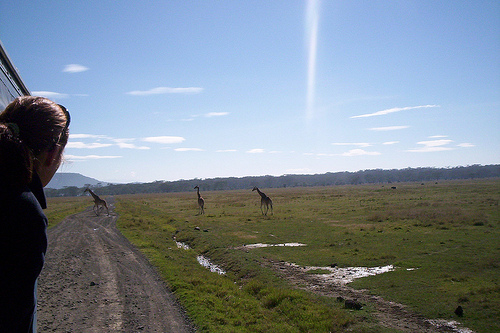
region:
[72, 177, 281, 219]
Three giraffes in front of the woman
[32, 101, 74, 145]
Glasses on the woman's head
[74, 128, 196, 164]
White clouds in the sky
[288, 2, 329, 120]
A thin white contrail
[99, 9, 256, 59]
The open blue sky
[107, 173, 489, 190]
Trees in the distance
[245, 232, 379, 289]
The plains are wet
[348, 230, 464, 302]
The grass is cut short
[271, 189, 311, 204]
Tall grass behind the giraffes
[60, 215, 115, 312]
A dirt path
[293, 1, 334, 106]
a white streak in the sky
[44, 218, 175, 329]
a brown dirt road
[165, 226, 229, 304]
water in a grassy ditch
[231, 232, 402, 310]
water puddles in the grassland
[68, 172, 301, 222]
three giraffes walking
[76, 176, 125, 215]
a giraffe crossing the road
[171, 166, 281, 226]
two giraffes following the first giraffe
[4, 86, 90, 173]
the back of a woman's head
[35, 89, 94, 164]
a pair of black sunglasses on a woman's head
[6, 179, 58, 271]
a blue sweater on a woman's shoulder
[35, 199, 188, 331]
a dirt road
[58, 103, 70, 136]
sunglasses on a woman's head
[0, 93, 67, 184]
brown hair pulled back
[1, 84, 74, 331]
a woman leaning out of a bus window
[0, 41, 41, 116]
the top of a bus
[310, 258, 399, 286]
watery mud in a field next to the road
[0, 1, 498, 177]
a blue sky with thin white clouds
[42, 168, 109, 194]
a mountain in the distance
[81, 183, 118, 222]
a giraffe on the road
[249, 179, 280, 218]
a giraffe in a field by the road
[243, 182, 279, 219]
giraffe in natural habitat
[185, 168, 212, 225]
giraffe in natural habitat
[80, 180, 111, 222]
giraffe in natural habitat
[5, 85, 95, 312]
person looking at giraffes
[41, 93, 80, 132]
sunglasses on top of head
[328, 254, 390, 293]
patch of water on field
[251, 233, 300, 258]
patch of water on field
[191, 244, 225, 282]
patch of water on field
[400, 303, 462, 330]
patch of water on field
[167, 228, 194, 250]
patch of water on field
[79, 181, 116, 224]
giraffe walking over the road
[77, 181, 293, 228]
group of giraffes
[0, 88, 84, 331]
person looking at a group of giraffes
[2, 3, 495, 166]
partially cloudy blue sky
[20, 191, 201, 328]
road through the countryside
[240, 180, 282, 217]
giraffe standing in a field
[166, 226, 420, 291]
muddy puddles in a field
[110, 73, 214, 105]
thin white cloud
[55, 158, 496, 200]
long line of trees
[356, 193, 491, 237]
tall brownish grass